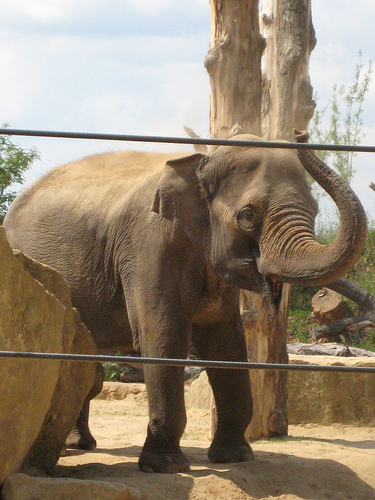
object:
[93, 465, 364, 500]
surface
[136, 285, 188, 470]
leg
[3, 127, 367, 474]
elephant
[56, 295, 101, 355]
edge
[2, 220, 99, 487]
wall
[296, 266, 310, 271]
part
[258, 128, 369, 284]
trunk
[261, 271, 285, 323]
mouth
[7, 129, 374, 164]
fence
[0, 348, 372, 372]
wire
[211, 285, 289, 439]
stump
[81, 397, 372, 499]
ground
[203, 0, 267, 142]
tree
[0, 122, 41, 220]
tree leaves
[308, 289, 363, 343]
tree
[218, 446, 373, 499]
shadow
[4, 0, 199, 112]
sky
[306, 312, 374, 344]
log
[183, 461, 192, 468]
edge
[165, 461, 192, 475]
toe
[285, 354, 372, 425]
boulder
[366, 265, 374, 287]
grass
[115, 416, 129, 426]
dirt